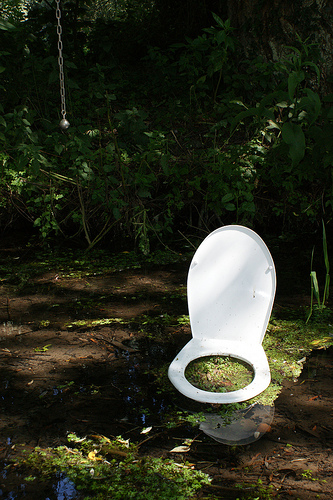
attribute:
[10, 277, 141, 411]
dirt —  ground,  brown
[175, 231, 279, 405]
lid — white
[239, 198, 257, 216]
leaf — green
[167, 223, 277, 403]
toilet seat — white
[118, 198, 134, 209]
leaf — green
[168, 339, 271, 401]
toilet seat — white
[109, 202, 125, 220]
leaf — green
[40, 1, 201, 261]
leaf — green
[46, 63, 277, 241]
bushes — dense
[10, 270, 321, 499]
dirt patch — brown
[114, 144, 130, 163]
leaf — green